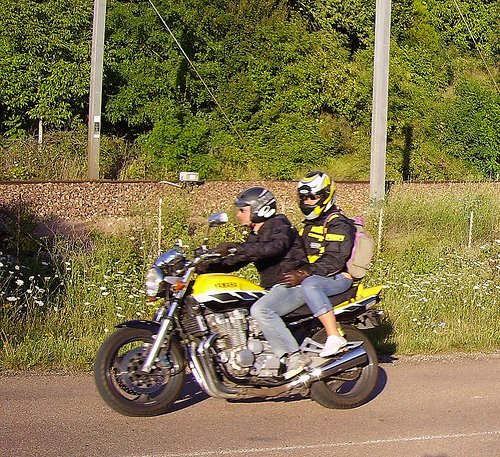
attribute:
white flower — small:
[16, 276, 23, 295]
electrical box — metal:
[179, 171, 202, 185]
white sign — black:
[91, 115, 104, 140]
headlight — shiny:
[142, 266, 162, 296]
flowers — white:
[1, 234, 493, 352]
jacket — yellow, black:
[294, 216, 356, 272]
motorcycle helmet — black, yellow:
[297, 171, 336, 220]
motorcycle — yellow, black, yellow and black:
[93, 210, 393, 416]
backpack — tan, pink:
[322, 208, 377, 278]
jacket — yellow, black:
[294, 207, 350, 274]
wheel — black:
[93, 324, 187, 416]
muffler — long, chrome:
[185, 330, 366, 396]